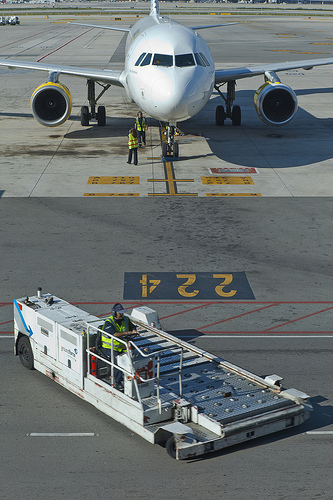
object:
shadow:
[0, 87, 332, 171]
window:
[173, 51, 196, 69]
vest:
[126, 128, 141, 151]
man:
[132, 109, 148, 148]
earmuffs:
[110, 300, 125, 318]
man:
[98, 297, 139, 394]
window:
[139, 52, 153, 66]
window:
[193, 49, 205, 68]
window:
[133, 52, 144, 64]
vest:
[100, 314, 130, 356]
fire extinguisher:
[88, 345, 97, 380]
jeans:
[101, 346, 124, 387]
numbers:
[212, 271, 237, 298]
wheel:
[171, 138, 181, 160]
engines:
[252, 79, 300, 128]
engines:
[28, 77, 73, 131]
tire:
[15, 333, 35, 371]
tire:
[96, 104, 106, 128]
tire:
[231, 104, 241, 132]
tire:
[166, 434, 175, 458]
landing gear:
[78, 79, 106, 131]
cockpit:
[133, 49, 210, 84]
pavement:
[0, 0, 332, 499]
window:
[151, 51, 173, 69]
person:
[124, 122, 139, 165]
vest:
[134, 115, 144, 132]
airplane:
[0, 1, 332, 161]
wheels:
[213, 103, 226, 128]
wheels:
[79, 105, 91, 126]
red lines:
[0, 327, 332, 339]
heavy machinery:
[12, 283, 313, 463]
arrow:
[13, 299, 34, 341]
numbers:
[172, 271, 198, 299]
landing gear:
[213, 80, 243, 130]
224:
[137, 272, 238, 301]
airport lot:
[0, 0, 332, 497]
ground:
[0, 0, 332, 498]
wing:
[214, 57, 332, 86]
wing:
[0, 60, 124, 89]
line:
[25, 430, 100, 439]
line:
[302, 430, 332, 437]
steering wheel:
[119, 330, 138, 343]